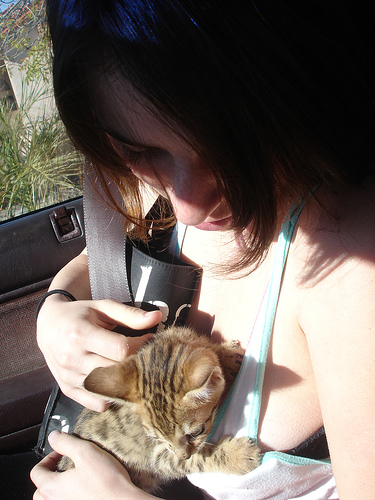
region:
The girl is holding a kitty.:
[75, 175, 286, 460]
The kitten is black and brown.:
[115, 338, 214, 477]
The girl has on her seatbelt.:
[50, 167, 348, 364]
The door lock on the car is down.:
[30, 207, 86, 254]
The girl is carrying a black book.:
[109, 244, 211, 337]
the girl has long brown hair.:
[147, 43, 329, 199]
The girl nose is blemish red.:
[165, 183, 221, 238]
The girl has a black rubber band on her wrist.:
[24, 291, 88, 321]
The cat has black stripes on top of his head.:
[145, 354, 184, 429]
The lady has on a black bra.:
[278, 430, 324, 461]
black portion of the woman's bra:
[293, 430, 340, 472]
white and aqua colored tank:
[239, 312, 277, 378]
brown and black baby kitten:
[19, 308, 274, 479]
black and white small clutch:
[100, 241, 210, 341]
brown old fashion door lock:
[46, 193, 90, 252]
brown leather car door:
[5, 208, 45, 431]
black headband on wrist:
[49, 287, 79, 322]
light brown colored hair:
[71, 16, 340, 189]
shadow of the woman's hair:
[308, 227, 343, 301]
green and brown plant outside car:
[7, 102, 53, 205]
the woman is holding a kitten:
[5, 0, 366, 380]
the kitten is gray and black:
[55, 324, 291, 486]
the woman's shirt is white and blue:
[188, 225, 358, 498]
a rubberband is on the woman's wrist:
[10, 265, 118, 363]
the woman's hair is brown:
[44, 2, 360, 247]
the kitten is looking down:
[81, 335, 293, 498]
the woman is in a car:
[1, 0, 371, 493]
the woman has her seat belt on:
[18, 144, 151, 454]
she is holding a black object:
[10, 227, 188, 499]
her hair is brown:
[45, 2, 353, 207]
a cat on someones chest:
[2, 245, 269, 498]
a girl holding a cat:
[6, 2, 327, 490]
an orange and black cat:
[33, 311, 289, 494]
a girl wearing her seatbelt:
[20, 107, 364, 487]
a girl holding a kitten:
[19, 12, 321, 498]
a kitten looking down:
[31, 287, 269, 498]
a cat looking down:
[54, 296, 245, 499]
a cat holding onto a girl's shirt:
[10, 256, 305, 487]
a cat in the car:
[14, 249, 330, 498]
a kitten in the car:
[32, 262, 279, 498]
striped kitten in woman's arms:
[33, 317, 266, 498]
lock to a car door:
[42, 200, 82, 243]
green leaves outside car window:
[3, 105, 61, 207]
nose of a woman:
[160, 177, 214, 232]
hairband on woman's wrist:
[24, 281, 85, 312]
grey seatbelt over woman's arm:
[73, 186, 140, 302]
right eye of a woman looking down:
[92, 124, 169, 175]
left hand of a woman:
[26, 427, 129, 499]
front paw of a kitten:
[217, 430, 266, 478]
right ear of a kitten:
[77, 355, 145, 406]